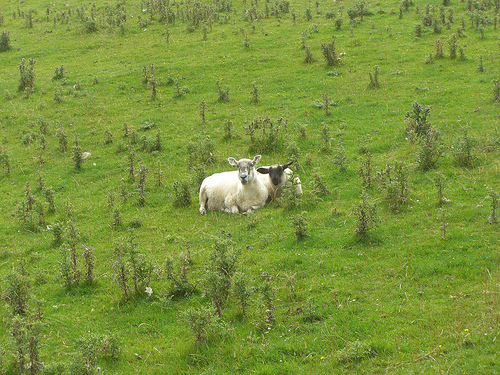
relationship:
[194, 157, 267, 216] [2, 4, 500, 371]
sheep sitting in a field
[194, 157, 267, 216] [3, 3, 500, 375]
sheep are on grass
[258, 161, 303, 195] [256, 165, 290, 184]
sheep has a black face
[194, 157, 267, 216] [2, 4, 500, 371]
sheep are in field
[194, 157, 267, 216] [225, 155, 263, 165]
sheep has ears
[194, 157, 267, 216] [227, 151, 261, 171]
sheep has eyes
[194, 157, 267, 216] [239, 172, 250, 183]
sheep has nose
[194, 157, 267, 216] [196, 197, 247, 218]
sheep has legs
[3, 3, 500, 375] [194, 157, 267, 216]
grass below sheep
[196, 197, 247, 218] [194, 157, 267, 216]
legs are below sheep